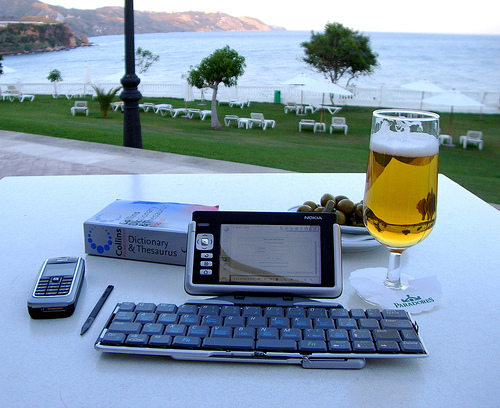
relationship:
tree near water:
[297, 18, 381, 105] [1, 29, 499, 111]